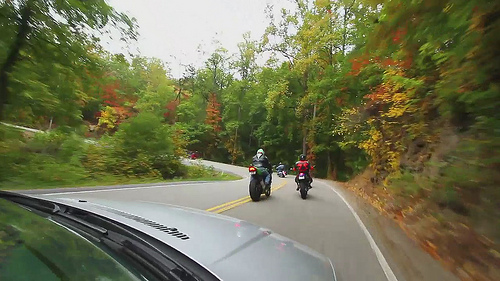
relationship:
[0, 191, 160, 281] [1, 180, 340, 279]
windshield in car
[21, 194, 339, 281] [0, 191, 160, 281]
hood in windshield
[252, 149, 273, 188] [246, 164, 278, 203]
biker riding motorcycle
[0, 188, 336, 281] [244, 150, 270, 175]
car following motorcycle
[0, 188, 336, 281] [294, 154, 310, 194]
car following motorcycle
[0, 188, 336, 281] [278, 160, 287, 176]
car following motorcycle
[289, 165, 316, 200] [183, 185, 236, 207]
motorcycle driving on a road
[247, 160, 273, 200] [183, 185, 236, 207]
motorcycle driving on a road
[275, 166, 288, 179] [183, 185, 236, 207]
motorcycle driving on a road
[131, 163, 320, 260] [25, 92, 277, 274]
hood of a car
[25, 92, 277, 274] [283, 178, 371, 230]
car on road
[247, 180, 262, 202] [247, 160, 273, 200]
tire on motorcycle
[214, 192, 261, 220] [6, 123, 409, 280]
line on road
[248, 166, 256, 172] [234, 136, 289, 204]
back headlight on motorcycle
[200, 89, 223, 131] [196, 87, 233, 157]
leaves on tree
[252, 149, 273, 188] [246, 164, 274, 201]
biker on bike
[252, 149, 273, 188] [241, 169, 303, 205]
biker in motorcycles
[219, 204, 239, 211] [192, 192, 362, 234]
yellow line on road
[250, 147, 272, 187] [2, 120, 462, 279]
biker down road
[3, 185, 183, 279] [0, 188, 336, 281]
windshield of car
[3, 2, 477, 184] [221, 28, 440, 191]
leaves on trees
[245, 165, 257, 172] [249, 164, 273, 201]
back headlight on bike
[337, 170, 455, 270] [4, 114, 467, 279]
bananas on ground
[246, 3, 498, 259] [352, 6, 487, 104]
trees with leaves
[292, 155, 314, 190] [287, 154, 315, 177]
biker in jacket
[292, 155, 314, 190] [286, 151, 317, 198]
biker riding motorcycle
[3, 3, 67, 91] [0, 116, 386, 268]
tree to left of road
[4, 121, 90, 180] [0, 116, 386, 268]
bush to left of road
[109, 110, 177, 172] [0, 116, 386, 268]
bush to left of road